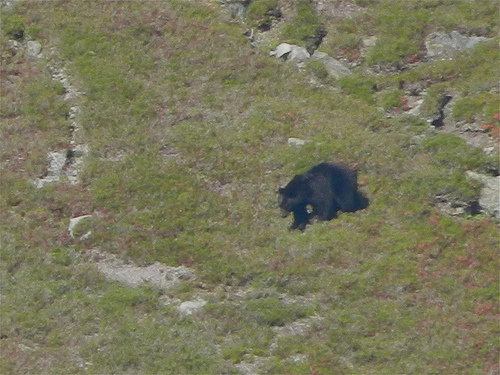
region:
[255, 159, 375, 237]
A black bear in grass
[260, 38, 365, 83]
Rocks behind the bear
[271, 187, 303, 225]
Head of a black bear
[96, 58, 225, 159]
Green grazing grasses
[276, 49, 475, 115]
A gulley in the grass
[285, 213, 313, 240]
Right leg of the bear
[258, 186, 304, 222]
Head of the black bear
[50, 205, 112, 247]
Gray rock in the grass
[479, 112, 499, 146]
Small orange flowers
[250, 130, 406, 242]
Black bear walking in the grass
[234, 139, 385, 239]
The bear is in the middle of the field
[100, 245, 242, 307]
Patches of dirt are in the field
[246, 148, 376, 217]
The bear has four legs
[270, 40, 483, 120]
Rocks sticking out of the grass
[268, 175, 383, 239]
The bear is a black bear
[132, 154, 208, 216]
The grass is green and patchy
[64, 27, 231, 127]
The side of the hill is grassy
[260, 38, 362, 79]
A large rock is on the hill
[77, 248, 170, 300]
Sand in the grass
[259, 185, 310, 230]
The bear has a brown nose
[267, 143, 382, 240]
bear walking in the grass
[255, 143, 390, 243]
fuzzy black bear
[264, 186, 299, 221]
head angled down towards the ground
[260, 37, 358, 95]
rock formation in the grass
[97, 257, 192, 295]
small patch of dirt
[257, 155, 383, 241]
bear on all fours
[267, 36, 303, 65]
rock in the grass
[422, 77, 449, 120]
grass growing on the rock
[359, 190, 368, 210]
shadow from the bear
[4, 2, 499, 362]
field of green grass that is thinning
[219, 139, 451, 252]
Bear in the wild.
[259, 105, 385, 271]
Black bear in the wild.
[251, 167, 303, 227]
Face of the bear.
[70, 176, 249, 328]
Gravel in the grass.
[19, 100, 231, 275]
Grass on the ground.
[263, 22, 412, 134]
Rocks on the ground.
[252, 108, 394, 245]
Fur on the bear.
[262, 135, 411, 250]
Bear walking on the grass.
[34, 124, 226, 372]
Rocks and gravel on the ground.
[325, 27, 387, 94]
Brown grass.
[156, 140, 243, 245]
part of a ground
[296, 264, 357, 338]
part of a ground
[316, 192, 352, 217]
edge of a pond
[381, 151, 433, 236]
part of a ground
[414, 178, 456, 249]
part of a ground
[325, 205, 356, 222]
edge of a pond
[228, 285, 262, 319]
part of a ground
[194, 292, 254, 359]
part of a ground